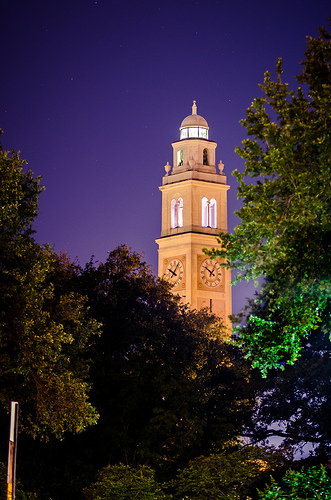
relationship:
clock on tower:
[196, 259, 226, 288] [139, 95, 247, 339]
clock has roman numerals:
[196, 259, 226, 288] [207, 259, 214, 267]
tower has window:
[139, 95, 247, 339] [200, 193, 219, 228]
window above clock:
[200, 193, 219, 228] [196, 259, 226, 288]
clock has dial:
[196, 259, 226, 288] [206, 264, 215, 276]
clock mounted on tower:
[196, 259, 226, 288] [139, 95, 247, 339]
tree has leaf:
[220, 23, 331, 378] [243, 140, 253, 150]